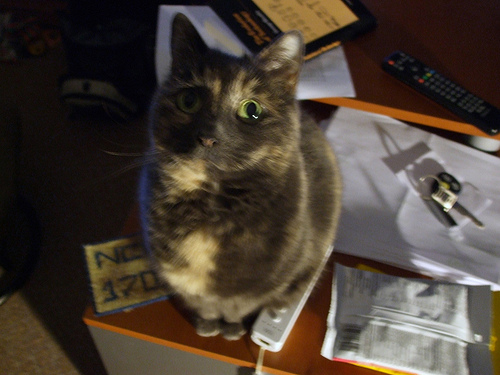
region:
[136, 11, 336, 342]
A cat standing on the desk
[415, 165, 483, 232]
Car keys on a stack of paper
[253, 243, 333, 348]
Nintendo Wii remote under a cat's foot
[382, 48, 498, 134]
A black remote on the desk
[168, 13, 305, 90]
Ears on a cat's head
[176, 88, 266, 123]
Green eyes on a cat's face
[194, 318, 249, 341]
Paws on a gray cat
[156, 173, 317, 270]
Gray fur on a cat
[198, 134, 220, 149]
Nose on a gray cat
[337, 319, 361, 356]
Barcode on the back of a plastic bag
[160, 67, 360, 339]
this is a cat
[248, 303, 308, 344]
this is a remote control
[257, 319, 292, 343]
the remote is white in color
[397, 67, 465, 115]
the remote is black in color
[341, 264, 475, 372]
this is a packet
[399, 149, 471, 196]
this is a key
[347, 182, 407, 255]
this is a paper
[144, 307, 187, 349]
this is a table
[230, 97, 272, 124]
eye of cat on desk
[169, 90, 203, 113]
eye of cat on desk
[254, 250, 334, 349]
white remote on desk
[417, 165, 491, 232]
keys sitting on desk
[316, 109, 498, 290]
papers on desk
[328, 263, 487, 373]
white packet on desk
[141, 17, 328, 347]
cat sitting on desk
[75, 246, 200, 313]
blue wood sign on desk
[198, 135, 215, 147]
pink nose of cat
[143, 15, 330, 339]
grey cat on desk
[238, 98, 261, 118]
green eye of cat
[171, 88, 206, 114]
green eye of cat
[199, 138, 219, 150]
pink nose of cat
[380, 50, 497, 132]
black remote on desk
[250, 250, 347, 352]
whii remote on desk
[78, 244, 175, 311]
brown sign on desk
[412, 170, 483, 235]
black keys on desk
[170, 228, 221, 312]
white chest of cat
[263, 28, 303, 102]
ear of cat on desk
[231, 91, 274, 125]
green and black eye of a cat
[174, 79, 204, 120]
green and black eye of a cat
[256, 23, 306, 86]
ear of a calico cat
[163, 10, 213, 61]
ear of a calico cat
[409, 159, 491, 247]
keys on a key chain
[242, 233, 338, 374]
white controller to a video game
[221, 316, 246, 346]
paw of a calico cat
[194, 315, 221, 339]
paw of a calico cat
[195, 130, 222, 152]
nose of a calico cat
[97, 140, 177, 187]
whiskers of a calico cat